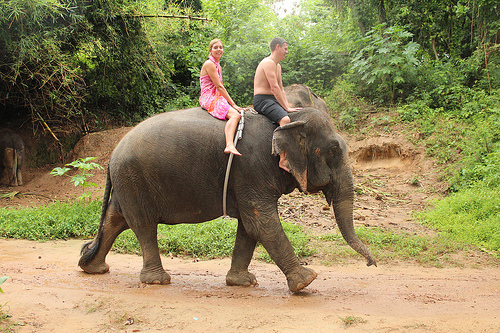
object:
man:
[252, 37, 293, 173]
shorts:
[253, 94, 290, 124]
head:
[269, 82, 377, 267]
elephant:
[77, 84, 378, 293]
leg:
[225, 211, 262, 287]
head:
[208, 37, 224, 57]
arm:
[203, 59, 235, 108]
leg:
[218, 101, 241, 148]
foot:
[224, 144, 242, 156]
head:
[269, 37, 290, 61]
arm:
[263, 61, 291, 110]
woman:
[197, 37, 243, 158]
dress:
[198, 54, 231, 121]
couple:
[197, 37, 302, 172]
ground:
[0, 235, 499, 332]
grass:
[407, 182, 499, 269]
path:
[0, 232, 499, 332]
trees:
[0, 0, 67, 123]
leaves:
[73, 43, 100, 66]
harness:
[222, 110, 247, 217]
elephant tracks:
[397, 283, 469, 305]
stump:
[1, 131, 28, 187]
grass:
[0, 193, 313, 264]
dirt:
[0, 235, 499, 331]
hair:
[209, 38, 224, 49]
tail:
[78, 161, 113, 269]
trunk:
[328, 180, 378, 269]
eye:
[326, 143, 341, 156]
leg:
[238, 205, 319, 294]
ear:
[271, 120, 309, 192]